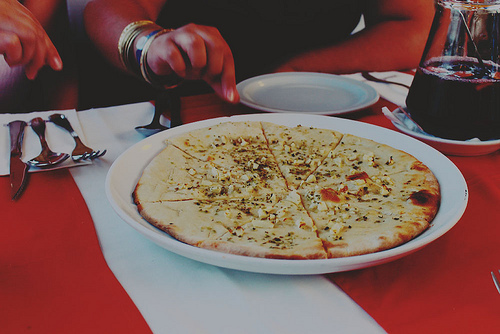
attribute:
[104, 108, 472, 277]
plate — white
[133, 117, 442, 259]
food — flatbread, delicious, topped, sliced, fresh, large, italian, white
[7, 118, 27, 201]
utensil — metal, knife, silver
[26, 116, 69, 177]
utensil — metal, spoon, silver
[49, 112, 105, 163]
utensil — metal, fork, silver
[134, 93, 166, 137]
utensil — silver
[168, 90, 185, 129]
utensil — silver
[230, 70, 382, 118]
plate — white, smaller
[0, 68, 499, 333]
table — set, red, white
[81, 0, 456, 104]
person — reaching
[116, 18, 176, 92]
bracelets — multicolored, colorful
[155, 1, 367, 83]
shirt — dark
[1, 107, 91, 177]
napkin — white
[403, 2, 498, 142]
pitcher — filled, glass, drink, wine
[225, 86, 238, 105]
fingernail — short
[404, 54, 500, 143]
drink — purple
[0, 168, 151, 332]
placemat — red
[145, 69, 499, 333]
placemat — red